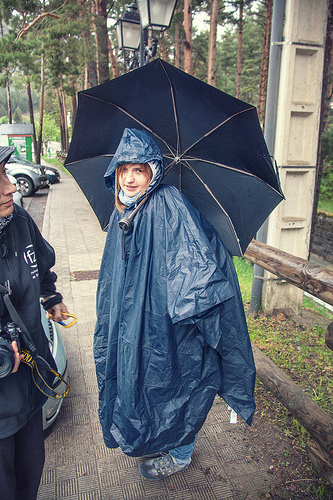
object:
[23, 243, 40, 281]
logo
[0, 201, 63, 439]
jacket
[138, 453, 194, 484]
shoe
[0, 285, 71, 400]
camera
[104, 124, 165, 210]
hood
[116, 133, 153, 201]
head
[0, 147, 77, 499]
man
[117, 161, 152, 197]
face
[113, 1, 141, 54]
lamp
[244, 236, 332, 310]
fence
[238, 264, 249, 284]
grass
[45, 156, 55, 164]
grass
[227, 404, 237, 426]
garbage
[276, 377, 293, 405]
part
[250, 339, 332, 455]
board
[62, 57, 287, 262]
umbrella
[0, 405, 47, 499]
pants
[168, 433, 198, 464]
jeans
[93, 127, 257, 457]
raincoat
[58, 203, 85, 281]
cement sidewalk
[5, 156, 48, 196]
vehicle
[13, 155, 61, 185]
vehicle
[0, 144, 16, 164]
hat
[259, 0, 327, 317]
column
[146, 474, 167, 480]
edge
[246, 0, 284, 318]
clips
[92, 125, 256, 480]
girl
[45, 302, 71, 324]
person's hand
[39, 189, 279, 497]
ground